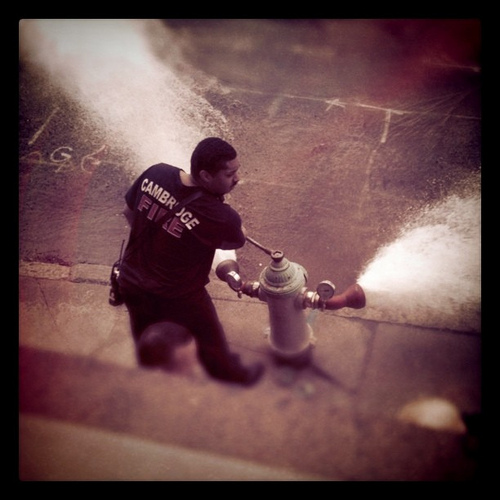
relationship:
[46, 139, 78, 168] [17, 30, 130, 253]
letter g on ground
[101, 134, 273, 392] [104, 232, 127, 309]
man has walkie talkie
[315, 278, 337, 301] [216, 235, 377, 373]
gauge on fire hydrant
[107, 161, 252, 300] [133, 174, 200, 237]
shirt says cambridge fire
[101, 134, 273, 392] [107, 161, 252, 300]
man has black shirt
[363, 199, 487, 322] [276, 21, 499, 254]
water spraying on street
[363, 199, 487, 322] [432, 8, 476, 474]
water spraying on left side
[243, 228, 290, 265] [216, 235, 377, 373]
wrench on fire hydrant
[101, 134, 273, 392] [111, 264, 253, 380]
man wearing pants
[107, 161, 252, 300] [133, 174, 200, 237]
shirt has writing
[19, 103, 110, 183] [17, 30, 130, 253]
drawing on street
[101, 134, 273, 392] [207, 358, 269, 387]
man wearing shoes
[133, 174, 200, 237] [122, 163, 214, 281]
strap on back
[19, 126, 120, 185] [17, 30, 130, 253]
drawing on sidewalk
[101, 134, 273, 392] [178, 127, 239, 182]
man has short hair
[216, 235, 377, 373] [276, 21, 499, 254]
fire hydrant on street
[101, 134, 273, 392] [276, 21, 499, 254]
man on street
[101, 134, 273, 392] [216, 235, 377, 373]
man flushing hydrant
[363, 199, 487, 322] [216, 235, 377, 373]
water from hydrant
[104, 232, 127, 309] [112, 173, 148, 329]
radio on side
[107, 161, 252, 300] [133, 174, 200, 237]
t shirt has writing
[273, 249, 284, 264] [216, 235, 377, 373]
bolt on a fire hydrant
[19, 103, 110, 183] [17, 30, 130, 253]
drawing on road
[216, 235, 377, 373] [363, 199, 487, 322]
fire hydrant with water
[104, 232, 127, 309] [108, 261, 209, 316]
walke-talkie on hip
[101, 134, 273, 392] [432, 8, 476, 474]
man looking to right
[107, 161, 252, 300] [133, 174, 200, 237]
t-shirt has name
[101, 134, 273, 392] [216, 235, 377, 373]
man opening fire hydrant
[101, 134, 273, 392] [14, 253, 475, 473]
man standing on sidewalk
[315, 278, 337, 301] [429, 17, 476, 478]
gauge in right side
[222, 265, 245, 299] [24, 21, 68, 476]
guage on left side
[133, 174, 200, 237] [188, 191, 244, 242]
strap on shoulder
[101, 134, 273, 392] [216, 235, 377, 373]
man testing fire hydrant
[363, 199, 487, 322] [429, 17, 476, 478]
water gushing from right side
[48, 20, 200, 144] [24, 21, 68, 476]
water gushing left side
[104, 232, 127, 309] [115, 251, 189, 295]
radio on belt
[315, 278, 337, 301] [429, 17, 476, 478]
gauge on right side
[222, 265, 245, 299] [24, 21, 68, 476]
gauge on left side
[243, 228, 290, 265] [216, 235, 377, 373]
tool to open hydrant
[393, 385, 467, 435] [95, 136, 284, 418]
head of man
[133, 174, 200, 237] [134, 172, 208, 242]
cambridge in letters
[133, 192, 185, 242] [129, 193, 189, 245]
fire in letters